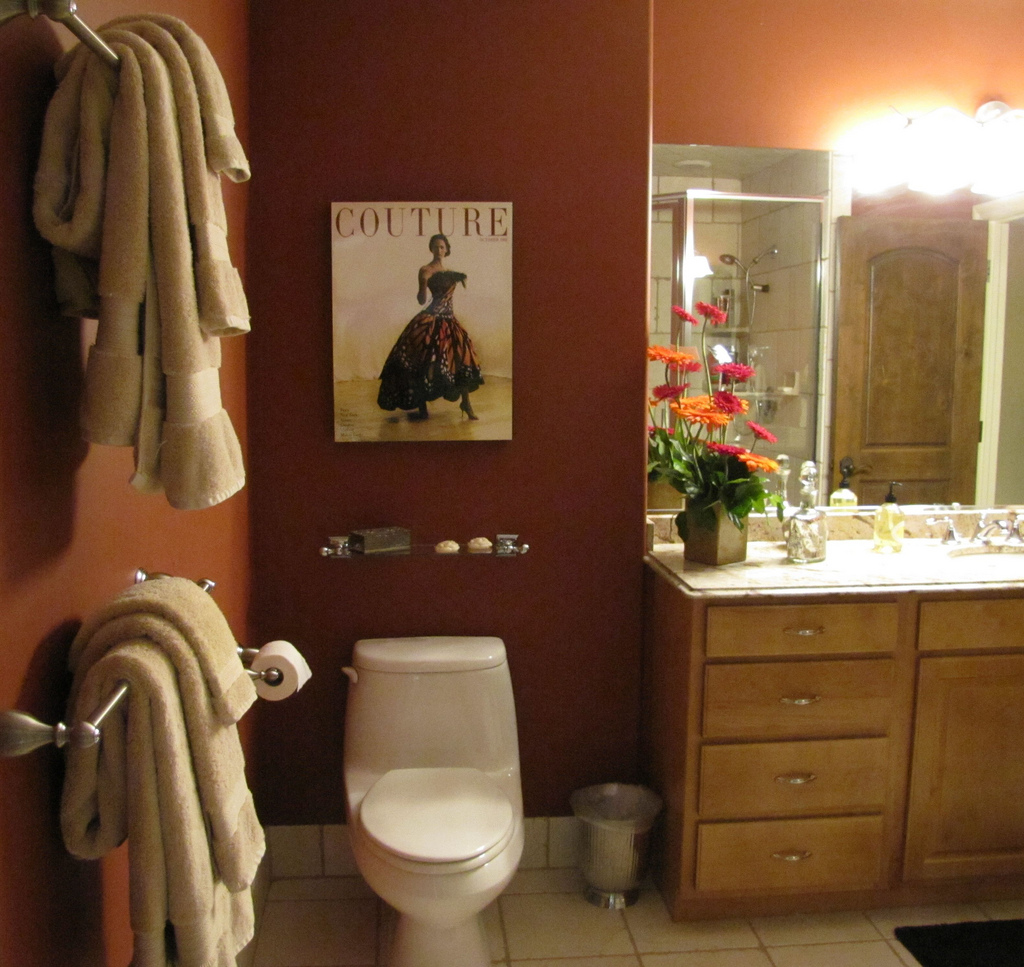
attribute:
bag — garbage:
[582, 767, 652, 817]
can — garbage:
[569, 750, 658, 900]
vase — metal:
[668, 489, 755, 569]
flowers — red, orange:
[637, 286, 776, 509]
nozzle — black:
[879, 476, 906, 507]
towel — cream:
[30, 7, 253, 520]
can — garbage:
[572, 775, 666, 922]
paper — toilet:
[244, 634, 307, 714]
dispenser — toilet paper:
[229, 641, 316, 700]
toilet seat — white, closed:
[343, 756, 527, 877]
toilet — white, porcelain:
[331, 626, 528, 964]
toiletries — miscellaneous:
[311, 521, 549, 554]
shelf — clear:
[303, 540, 543, 571]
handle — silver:
[765, 616, 833, 643]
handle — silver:
[765, 678, 830, 718]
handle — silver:
[771, 763, 817, 792]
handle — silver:
[756, 842, 819, 875]